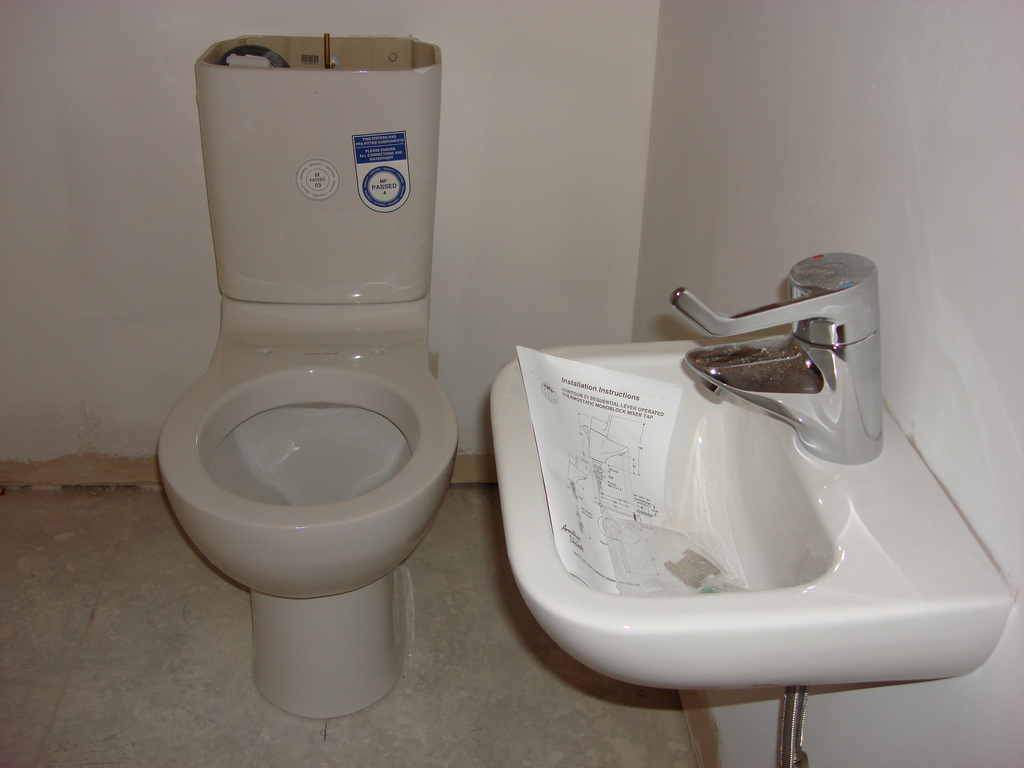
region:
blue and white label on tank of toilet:
[341, 128, 421, 231]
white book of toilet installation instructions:
[526, 349, 688, 485]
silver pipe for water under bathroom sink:
[777, 682, 825, 763]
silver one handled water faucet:
[667, 273, 788, 350]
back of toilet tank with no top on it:
[179, 18, 467, 104]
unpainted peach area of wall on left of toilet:
[38, 438, 166, 499]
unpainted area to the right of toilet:
[458, 440, 494, 502]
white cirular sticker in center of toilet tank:
[297, 145, 336, 207]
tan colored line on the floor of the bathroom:
[49, 594, 101, 766]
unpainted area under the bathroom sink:
[673, 690, 731, 757]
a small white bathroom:
[8, 7, 1014, 754]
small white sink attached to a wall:
[475, 174, 1011, 732]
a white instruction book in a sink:
[495, 236, 945, 661]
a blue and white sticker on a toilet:
[280, 121, 481, 518]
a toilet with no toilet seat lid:
[108, 29, 482, 734]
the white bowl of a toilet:
[134, 320, 528, 750]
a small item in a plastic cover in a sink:
[503, 338, 798, 668]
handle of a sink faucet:
[649, 205, 887, 377]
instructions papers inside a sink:
[512, 342, 754, 596]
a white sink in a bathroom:
[488, 343, 1016, 697]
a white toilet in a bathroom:
[156, 34, 463, 717]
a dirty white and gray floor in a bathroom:
[5, 497, 699, 764]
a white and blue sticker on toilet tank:
[348, 128, 409, 209]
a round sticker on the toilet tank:
[294, 157, 340, 206]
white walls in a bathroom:
[2, 5, 1018, 765]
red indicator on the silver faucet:
[811, 251, 828, 267]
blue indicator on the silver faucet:
[838, 273, 855, 290]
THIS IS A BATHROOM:
[403, 516, 682, 518]